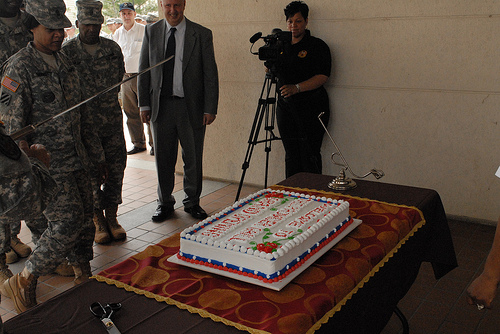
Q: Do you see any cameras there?
A: Yes, there is a camera.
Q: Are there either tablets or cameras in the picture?
A: Yes, there is a camera.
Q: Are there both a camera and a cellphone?
A: No, there is a camera but no cell phones.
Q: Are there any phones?
A: No, there are no phones.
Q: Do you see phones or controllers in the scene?
A: No, there are no phones or controllers.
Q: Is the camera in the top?
A: Yes, the camera is in the top of the image.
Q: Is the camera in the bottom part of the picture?
A: No, the camera is in the top of the image.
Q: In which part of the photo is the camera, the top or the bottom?
A: The camera is in the top of the image.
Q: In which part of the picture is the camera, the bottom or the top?
A: The camera is in the top of the image.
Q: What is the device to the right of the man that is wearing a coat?
A: The device is a camera.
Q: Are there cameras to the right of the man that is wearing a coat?
A: Yes, there is a camera to the right of the man.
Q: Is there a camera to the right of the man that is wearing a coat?
A: Yes, there is a camera to the right of the man.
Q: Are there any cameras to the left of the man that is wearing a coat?
A: No, the camera is to the right of the man.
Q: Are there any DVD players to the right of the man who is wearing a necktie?
A: No, there is a camera to the right of the man.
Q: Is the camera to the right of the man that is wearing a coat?
A: Yes, the camera is to the right of the man.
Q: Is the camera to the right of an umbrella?
A: No, the camera is to the right of the man.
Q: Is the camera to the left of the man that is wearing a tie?
A: No, the camera is to the right of the man.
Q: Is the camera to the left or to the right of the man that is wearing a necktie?
A: The camera is to the right of the man.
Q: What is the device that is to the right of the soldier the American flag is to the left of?
A: The device is a camera.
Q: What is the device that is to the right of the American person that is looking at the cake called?
A: The device is a camera.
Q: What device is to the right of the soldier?
A: The device is a camera.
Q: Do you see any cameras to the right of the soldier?
A: Yes, there is a camera to the right of the soldier.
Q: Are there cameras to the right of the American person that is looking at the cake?
A: Yes, there is a camera to the right of the soldier.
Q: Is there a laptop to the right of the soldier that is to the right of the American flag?
A: No, there is a camera to the right of the soldier.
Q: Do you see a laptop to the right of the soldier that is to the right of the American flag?
A: No, there is a camera to the right of the soldier.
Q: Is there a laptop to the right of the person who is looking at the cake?
A: No, there is a camera to the right of the soldier.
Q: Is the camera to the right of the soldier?
A: Yes, the camera is to the right of the soldier.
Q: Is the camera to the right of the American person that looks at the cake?
A: Yes, the camera is to the right of the soldier.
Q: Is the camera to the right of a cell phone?
A: No, the camera is to the right of the soldier.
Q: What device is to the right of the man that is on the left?
A: The device is a camera.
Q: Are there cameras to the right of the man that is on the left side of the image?
A: Yes, there is a camera to the right of the man.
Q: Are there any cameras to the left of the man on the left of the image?
A: No, the camera is to the right of the man.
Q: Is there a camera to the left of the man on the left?
A: No, the camera is to the right of the man.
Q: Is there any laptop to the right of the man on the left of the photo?
A: No, there is a camera to the right of the man.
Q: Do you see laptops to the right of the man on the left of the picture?
A: No, there is a camera to the right of the man.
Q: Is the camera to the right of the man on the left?
A: Yes, the camera is to the right of the man.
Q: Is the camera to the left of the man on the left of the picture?
A: No, the camera is to the right of the man.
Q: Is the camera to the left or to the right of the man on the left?
A: The camera is to the right of the man.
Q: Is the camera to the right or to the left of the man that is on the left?
A: The camera is to the right of the man.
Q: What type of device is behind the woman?
A: The device is a camera.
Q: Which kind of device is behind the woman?
A: The device is a camera.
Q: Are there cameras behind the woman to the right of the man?
A: Yes, there is a camera behind the woman.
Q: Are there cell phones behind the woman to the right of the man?
A: No, there is a camera behind the woman.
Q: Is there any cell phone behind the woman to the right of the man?
A: No, there is a camera behind the woman.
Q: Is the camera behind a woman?
A: Yes, the camera is behind a woman.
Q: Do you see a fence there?
A: No, there are no fences.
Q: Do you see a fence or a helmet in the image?
A: No, there are no fences or helmets.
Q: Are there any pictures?
A: No, there are no pictures.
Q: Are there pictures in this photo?
A: No, there are no pictures.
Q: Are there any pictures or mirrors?
A: No, there are no pictures or mirrors.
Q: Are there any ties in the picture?
A: Yes, there is a tie.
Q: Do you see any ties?
A: Yes, there is a tie.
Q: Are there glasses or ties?
A: Yes, there is a tie.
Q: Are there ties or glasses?
A: Yes, there is a tie.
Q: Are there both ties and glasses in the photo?
A: No, there is a tie but no glasses.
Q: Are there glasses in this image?
A: No, there are no glasses.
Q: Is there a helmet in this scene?
A: No, there are no helmets.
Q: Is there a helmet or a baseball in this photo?
A: No, there are no helmets or baseballs.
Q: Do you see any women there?
A: Yes, there is a woman.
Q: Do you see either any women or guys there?
A: Yes, there is a woman.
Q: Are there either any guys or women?
A: Yes, there is a woman.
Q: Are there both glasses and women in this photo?
A: No, there is a woman but no glasses.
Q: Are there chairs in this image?
A: No, there are no chairs.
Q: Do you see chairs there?
A: No, there are no chairs.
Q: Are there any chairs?
A: No, there are no chairs.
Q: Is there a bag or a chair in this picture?
A: No, there are no chairs or bags.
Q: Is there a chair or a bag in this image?
A: No, there are no chairs or bags.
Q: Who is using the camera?
A: The woman is using the camera.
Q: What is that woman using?
A: The woman is using a camera.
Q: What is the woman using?
A: The woman is using a camera.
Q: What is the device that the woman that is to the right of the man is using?
A: The device is a camera.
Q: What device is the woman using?
A: The woman is using a camera.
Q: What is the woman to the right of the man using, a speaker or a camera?
A: The woman is using a camera.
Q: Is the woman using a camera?
A: Yes, the woman is using a camera.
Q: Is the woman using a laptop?
A: No, the woman is using a camera.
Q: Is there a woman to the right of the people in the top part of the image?
A: Yes, there is a woman to the right of the people.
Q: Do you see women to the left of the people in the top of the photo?
A: No, the woman is to the right of the people.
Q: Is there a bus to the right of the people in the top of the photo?
A: No, there is a woman to the right of the people.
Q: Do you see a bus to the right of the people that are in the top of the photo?
A: No, there is a woman to the right of the people.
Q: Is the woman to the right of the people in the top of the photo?
A: Yes, the woman is to the right of the people.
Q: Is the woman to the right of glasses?
A: No, the woman is to the right of the people.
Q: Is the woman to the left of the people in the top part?
A: No, the woman is to the right of the people.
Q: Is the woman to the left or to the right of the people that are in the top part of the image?
A: The woman is to the right of the people.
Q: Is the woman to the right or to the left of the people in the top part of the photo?
A: The woman is to the right of the people.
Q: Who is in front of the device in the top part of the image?
A: The woman is in front of the camera.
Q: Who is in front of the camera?
A: The woman is in front of the camera.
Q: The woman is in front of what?
A: The woman is in front of the camera.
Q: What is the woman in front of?
A: The woman is in front of the camera.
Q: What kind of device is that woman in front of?
A: The woman is in front of the camera.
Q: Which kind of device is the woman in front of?
A: The woman is in front of the camera.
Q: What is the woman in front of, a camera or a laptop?
A: The woman is in front of a camera.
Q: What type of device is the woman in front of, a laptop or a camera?
A: The woman is in front of a camera.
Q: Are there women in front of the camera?
A: Yes, there is a woman in front of the camera.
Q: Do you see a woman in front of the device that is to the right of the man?
A: Yes, there is a woman in front of the camera.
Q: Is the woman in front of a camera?
A: Yes, the woman is in front of a camera.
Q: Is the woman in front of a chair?
A: No, the woman is in front of a camera.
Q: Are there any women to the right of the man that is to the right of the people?
A: Yes, there is a woman to the right of the man.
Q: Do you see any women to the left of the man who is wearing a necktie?
A: No, the woman is to the right of the man.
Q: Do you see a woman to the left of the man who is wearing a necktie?
A: No, the woman is to the right of the man.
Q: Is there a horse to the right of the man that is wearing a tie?
A: No, there is a woman to the right of the man.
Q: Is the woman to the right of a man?
A: Yes, the woman is to the right of a man.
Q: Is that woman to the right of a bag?
A: No, the woman is to the right of a man.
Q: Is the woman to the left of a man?
A: No, the woman is to the right of a man.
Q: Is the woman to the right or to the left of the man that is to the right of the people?
A: The woman is to the right of the man.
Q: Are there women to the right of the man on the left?
A: Yes, there is a woman to the right of the man.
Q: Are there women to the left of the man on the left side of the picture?
A: No, the woman is to the right of the man.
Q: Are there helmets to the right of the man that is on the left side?
A: No, there is a woman to the right of the man.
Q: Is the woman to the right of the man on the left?
A: Yes, the woman is to the right of the man.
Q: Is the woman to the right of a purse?
A: No, the woman is to the right of the man.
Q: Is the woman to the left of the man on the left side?
A: No, the woman is to the right of the man.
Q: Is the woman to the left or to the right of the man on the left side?
A: The woman is to the right of the man.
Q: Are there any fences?
A: No, there are no fences.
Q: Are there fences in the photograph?
A: No, there are no fences.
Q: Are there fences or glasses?
A: No, there are no fences or glasses.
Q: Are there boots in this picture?
A: Yes, there are boots.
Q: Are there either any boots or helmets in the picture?
A: Yes, there are boots.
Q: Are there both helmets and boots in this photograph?
A: No, there are boots but no helmets.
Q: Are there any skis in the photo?
A: No, there are no skis.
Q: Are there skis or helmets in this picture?
A: No, there are no skis or helmets.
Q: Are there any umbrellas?
A: No, there are no umbrellas.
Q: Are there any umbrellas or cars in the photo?
A: No, there are no umbrellas or cars.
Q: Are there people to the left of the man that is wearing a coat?
A: Yes, there are people to the left of the man.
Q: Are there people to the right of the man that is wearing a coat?
A: No, the people are to the left of the man.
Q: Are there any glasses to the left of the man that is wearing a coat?
A: No, there are people to the left of the man.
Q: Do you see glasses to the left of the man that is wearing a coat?
A: No, there are people to the left of the man.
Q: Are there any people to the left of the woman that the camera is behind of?
A: Yes, there are people to the left of the woman.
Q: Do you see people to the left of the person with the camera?
A: Yes, there are people to the left of the woman.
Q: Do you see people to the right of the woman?
A: No, the people are to the left of the woman.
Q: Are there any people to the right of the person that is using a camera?
A: No, the people are to the left of the woman.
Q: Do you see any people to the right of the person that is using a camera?
A: No, the people are to the left of the woman.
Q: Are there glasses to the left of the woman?
A: No, there are people to the left of the woman.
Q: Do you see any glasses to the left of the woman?
A: No, there are people to the left of the woman.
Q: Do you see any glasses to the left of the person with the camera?
A: No, there are people to the left of the woman.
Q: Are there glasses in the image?
A: No, there are no glasses.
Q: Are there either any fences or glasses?
A: No, there are no glasses or fences.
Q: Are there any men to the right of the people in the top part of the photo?
A: Yes, there is a man to the right of the people.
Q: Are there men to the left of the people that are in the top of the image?
A: No, the man is to the right of the people.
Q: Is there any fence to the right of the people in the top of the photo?
A: No, there is a man to the right of the people.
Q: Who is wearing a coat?
A: The man is wearing a coat.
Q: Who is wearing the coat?
A: The man is wearing a coat.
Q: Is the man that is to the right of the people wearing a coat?
A: Yes, the man is wearing a coat.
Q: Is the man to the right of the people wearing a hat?
A: No, the man is wearing a coat.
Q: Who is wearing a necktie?
A: The man is wearing a necktie.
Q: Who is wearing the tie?
A: The man is wearing a necktie.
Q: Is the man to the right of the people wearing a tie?
A: Yes, the man is wearing a tie.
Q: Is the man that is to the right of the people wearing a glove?
A: No, the man is wearing a tie.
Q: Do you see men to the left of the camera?
A: Yes, there is a man to the left of the camera.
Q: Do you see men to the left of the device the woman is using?
A: Yes, there is a man to the left of the camera.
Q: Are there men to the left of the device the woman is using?
A: Yes, there is a man to the left of the camera.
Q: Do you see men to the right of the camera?
A: No, the man is to the left of the camera.